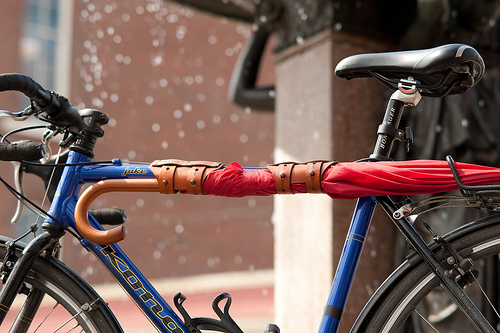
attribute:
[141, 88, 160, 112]
speck — small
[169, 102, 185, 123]
speck — small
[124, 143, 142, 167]
speck — small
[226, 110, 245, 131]
speck — small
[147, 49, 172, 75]
speck — small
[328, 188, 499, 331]
tire — black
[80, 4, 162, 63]
specks — small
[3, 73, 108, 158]
handles — black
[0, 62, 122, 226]
handle bars — red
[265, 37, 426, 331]
wall — grey, corner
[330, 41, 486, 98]
seat — black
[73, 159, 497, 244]
umbrella — red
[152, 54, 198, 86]
specks — small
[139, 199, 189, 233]
specks — small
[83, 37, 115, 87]
specks — small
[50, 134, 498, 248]
umbrella — red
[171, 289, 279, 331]
holder — black, water bottle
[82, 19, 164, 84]
specks — small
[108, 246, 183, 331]
name — black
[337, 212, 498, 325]
tire — rear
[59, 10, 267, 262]
specks — small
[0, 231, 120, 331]
wheel — black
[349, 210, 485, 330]
wheel — black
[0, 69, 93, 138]
handlebars — black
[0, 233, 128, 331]
tire — black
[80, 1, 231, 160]
specks — small